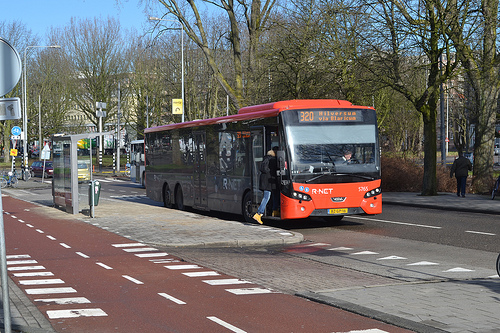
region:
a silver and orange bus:
[140, 91, 382, 223]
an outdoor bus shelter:
[46, 128, 110, 217]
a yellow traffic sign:
[168, 94, 185, 119]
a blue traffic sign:
[6, 120, 22, 185]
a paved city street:
[49, 161, 499, 285]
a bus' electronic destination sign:
[291, 108, 362, 125]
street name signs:
[93, 96, 110, 165]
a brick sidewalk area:
[43, 190, 285, 247]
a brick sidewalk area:
[323, 276, 496, 331]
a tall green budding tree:
[373, 2, 475, 188]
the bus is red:
[112, 83, 397, 285]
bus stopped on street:
[132, 97, 385, 231]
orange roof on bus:
[245, 94, 360, 115]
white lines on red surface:
[73, 243, 153, 295]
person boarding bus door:
[247, 150, 279, 232]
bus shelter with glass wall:
[45, 127, 107, 217]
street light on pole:
[146, 10, 198, 76]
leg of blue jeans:
[252, 185, 274, 221]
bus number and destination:
[286, 105, 366, 132]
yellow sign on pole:
[166, 90, 189, 120]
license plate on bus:
[317, 201, 354, 221]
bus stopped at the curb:
[125, 86, 402, 230]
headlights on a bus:
[288, 188, 320, 205]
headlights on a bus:
[361, 184, 384, 202]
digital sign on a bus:
[292, 104, 372, 127]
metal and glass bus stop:
[36, 123, 124, 222]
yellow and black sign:
[167, 94, 184, 121]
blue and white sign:
[9, 122, 26, 138]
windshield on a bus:
[281, 118, 384, 179]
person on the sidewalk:
[447, 148, 477, 201]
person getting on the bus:
[245, 144, 290, 233]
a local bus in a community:
[5, 8, 495, 323]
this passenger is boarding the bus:
[200, 117, 386, 266]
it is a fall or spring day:
[15, 5, 491, 193]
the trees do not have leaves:
[15, 15, 497, 107]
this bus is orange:
[135, 90, 416, 252]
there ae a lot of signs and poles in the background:
[6, 81, 171, 232]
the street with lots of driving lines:
[15, 172, 496, 318]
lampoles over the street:
[18, 11, 199, 102]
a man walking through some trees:
[416, 101, 497, 224]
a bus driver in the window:
[301, 96, 436, 243]